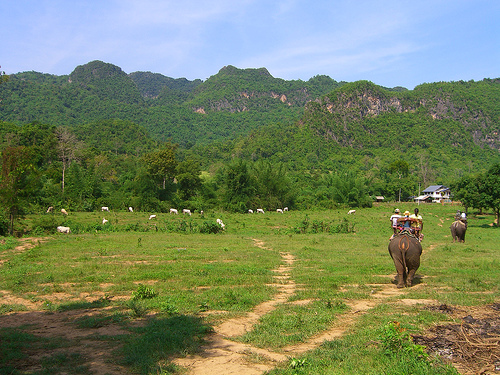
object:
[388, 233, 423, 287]
elephant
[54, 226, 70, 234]
herd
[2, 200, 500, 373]
grass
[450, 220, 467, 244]
elephant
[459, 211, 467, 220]
people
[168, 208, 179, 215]
animal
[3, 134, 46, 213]
trees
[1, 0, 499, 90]
sky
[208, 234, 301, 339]
path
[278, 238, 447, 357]
path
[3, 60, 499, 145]
mountain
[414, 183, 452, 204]
house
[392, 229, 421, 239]
cloth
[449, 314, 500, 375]
pool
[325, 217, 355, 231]
shrubs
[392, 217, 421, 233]
bench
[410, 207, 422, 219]
woman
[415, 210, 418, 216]
pony tail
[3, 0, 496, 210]
background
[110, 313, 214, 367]
grass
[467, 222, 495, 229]
shadow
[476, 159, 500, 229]
tree